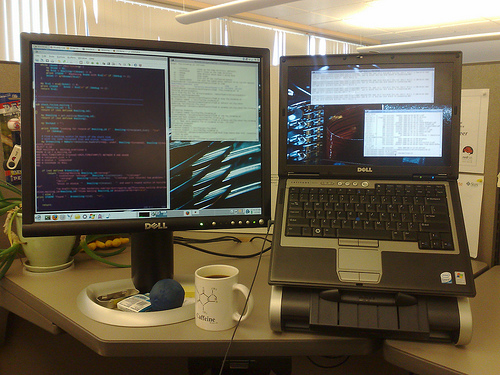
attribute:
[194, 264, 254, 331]
coffee cup — here, white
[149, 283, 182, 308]
ball — blue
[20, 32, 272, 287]
monitor — here, black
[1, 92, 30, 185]
pez dispenser — here, packaged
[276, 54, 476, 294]
laptop — here, black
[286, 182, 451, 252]
keyboard — here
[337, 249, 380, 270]
touch pad — here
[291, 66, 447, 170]
screen — here, on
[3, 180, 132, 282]
plant — potted, green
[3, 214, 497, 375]
desk — here, wooden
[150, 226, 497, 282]
wires — black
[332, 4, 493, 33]
flourescent light — long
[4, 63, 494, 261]
wall — here